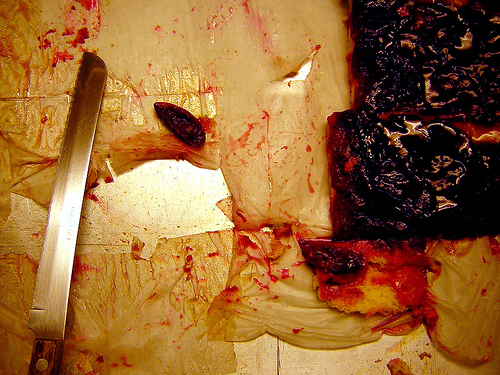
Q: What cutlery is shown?
A: Knife.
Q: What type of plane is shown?
A: No plane.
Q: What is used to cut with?
A: A knife.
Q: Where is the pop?
A: No pop.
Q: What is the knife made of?
A: Metal and wood.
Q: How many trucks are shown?
A: There are no trucks.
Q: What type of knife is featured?
A: A large knife that has a jagged edge.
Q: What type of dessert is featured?
A: Cake with red fruit sauce.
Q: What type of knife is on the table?
A: A large bread-cutting knife.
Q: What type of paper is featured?
A: Parchment paper that has been wrinkled due to moisture.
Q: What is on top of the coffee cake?
A: Plum jelly sauce.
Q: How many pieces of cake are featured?
A: Two pieces with plum jelly on top.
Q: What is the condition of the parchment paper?
A: It has a large tear in it.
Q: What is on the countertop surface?
A: Residue from the plum jelly.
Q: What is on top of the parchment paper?
A: A small piece of cake that is layered with plum jelly.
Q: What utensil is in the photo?
A: Knife.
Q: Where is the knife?
A: Hard surface.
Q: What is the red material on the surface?
A: Jelly and sauce.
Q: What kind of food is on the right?
A: Bread.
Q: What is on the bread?
A: Jelly.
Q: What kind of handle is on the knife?
A: Wooden handle.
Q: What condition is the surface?
A: Dirty.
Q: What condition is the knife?
A: Clean.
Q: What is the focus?
A: Bloody carving board.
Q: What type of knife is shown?
A: Bread knife.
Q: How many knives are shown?
A: 1.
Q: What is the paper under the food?
A: Parchment.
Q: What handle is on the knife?
A: Wooden.